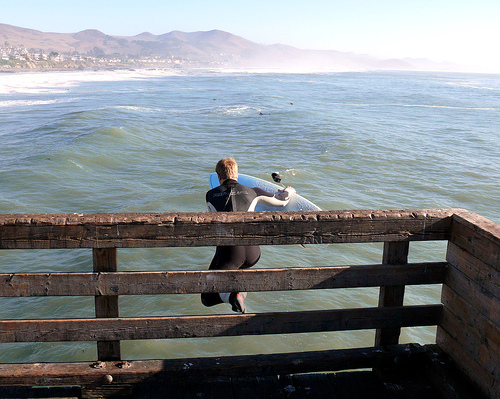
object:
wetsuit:
[199, 179, 293, 308]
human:
[200, 157, 296, 314]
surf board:
[209, 172, 322, 211]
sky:
[0, 0, 499, 60]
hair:
[215, 156, 238, 180]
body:
[0, 71, 500, 211]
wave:
[99, 105, 154, 113]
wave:
[211, 105, 262, 117]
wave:
[0, 95, 79, 107]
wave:
[1, 66, 188, 93]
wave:
[440, 75, 499, 90]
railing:
[0, 208, 499, 399]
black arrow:
[201, 179, 291, 314]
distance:
[3, 0, 315, 91]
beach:
[0, 66, 494, 78]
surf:
[0, 65, 364, 88]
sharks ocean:
[209, 166, 322, 212]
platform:
[28, 377, 500, 398]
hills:
[0, 22, 430, 67]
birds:
[212, 98, 293, 115]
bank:
[0, 59, 103, 73]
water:
[0, 70, 499, 397]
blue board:
[208, 171, 322, 211]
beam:
[0, 208, 450, 250]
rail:
[0, 208, 450, 251]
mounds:
[0, 70, 499, 361]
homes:
[0, 53, 180, 66]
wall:
[432, 202, 499, 391]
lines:
[0, 227, 442, 243]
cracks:
[0, 224, 414, 245]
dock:
[1, 207, 499, 398]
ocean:
[0, 72, 499, 361]